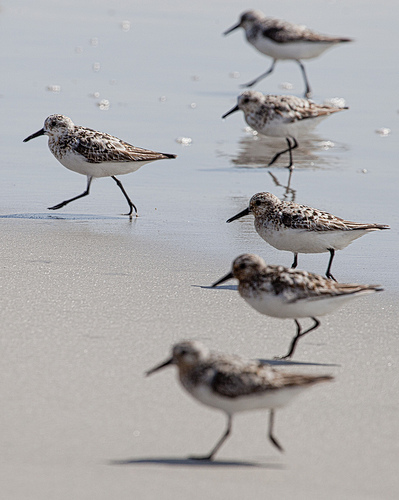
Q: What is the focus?
A: Birds running from the tide.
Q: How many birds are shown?
A: 6.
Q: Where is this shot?
A: Beach.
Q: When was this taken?
A: Daytime.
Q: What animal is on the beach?
A: Birds.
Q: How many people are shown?
A: 0.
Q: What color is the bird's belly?
A: White.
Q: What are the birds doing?
A: Running.